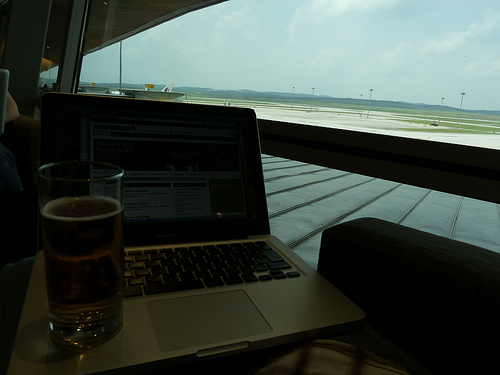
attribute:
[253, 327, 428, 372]
seat — comfortable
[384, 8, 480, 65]
cloud — white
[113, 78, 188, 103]
boat — gray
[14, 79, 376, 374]
computer — modern, sleek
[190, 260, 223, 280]
key — black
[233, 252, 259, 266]
key — black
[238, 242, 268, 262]
key — black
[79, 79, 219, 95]
hill — mountainous, extensive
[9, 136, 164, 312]
beer sitting — bubbly, fizzy, full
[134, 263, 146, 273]
key — black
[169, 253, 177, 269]
key — black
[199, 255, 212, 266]
key — black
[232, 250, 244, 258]
key — black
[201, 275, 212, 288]
key — black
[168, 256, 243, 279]
keys — black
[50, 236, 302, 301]
keyboard — small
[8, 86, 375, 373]
laptop — grey, black, compact, sleek, modern, practical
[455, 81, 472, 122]
pole — tall, silver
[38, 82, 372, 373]
laptop — small, grey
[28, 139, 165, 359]
glass — empty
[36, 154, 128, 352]
glass — cylindrical, transparent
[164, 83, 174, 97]
tail — white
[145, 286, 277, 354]
track pad — rectangular, silver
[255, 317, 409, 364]
plaid — printed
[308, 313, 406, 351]
material — plaid